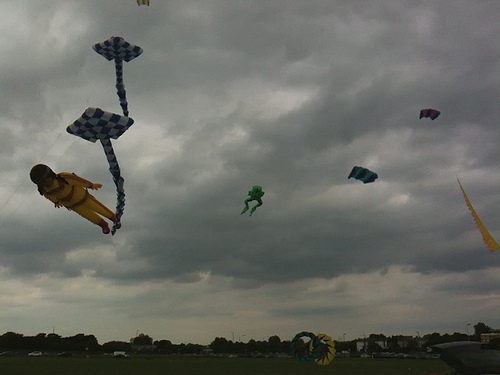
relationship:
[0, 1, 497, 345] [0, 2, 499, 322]
clouds in sky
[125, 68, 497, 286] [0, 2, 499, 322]
cloud in sky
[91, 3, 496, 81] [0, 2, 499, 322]
cloud in sky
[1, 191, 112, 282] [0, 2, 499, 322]
cloud in sky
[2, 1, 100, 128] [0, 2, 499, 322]
cloud in sky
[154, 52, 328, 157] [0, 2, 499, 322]
clouds in sky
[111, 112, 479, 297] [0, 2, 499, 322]
clouds in sky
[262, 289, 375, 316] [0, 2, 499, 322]
cloud in sky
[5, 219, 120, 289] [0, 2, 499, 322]
cloud in sky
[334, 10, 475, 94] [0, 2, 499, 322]
cloud in sky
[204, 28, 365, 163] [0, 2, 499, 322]
cloud in sky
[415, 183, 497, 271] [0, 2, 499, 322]
cloud in sky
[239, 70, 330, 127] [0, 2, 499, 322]
cloud in sky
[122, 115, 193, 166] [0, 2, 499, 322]
cloud in sky